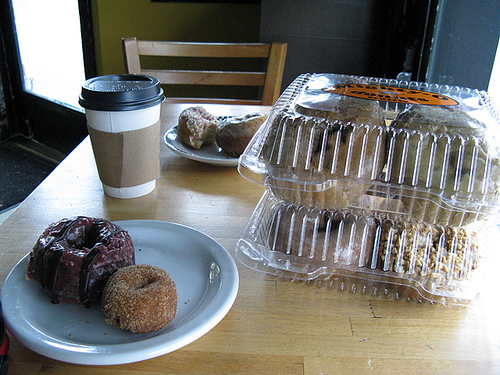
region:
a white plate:
[20, 204, 240, 371]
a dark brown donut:
[22, 205, 132, 293]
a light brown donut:
[93, 259, 183, 341]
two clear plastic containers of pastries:
[258, 67, 463, 316]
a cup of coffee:
[55, 31, 172, 219]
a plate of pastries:
[158, 92, 260, 167]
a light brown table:
[41, 84, 485, 359]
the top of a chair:
[73, 13, 295, 123]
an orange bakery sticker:
[327, 75, 461, 121]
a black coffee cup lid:
[68, 54, 168, 111]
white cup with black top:
[103, 100, 113, 130]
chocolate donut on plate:
[42, 250, 115, 285]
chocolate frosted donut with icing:
[39, 230, 135, 270]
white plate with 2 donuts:
[191, 256, 225, 304]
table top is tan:
[276, 320, 312, 331]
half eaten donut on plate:
[190, 113, 208, 163]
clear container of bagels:
[314, 135, 390, 182]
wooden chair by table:
[211, 43, 253, 87]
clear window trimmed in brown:
[33, 43, 55, 63]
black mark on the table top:
[348, 298, 395, 319]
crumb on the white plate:
[133, 243, 159, 253]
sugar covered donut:
[102, 267, 188, 321]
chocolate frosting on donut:
[30, 217, 129, 279]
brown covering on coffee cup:
[73, 118, 184, 186]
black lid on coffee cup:
[73, 68, 161, 110]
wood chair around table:
[114, 28, 304, 123]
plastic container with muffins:
[240, 65, 479, 219]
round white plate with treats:
[4, 217, 267, 354]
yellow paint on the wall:
[132, 9, 233, 23]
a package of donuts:
[240, 72, 495, 222]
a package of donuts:
[235, 176, 475, 306]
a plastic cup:
[80, 75, 162, 195]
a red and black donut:
[30, 212, 135, 307]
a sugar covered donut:
[102, 263, 177, 335]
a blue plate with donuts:
[4, 218, 239, 366]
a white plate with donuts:
[166, 105, 268, 165]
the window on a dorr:
[7, 0, 88, 112]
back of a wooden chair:
[120, 33, 280, 103]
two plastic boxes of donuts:
[232, 68, 498, 309]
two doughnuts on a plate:
[31, 210, 172, 333]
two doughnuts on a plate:
[175, 105, 253, 157]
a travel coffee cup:
[79, 69, 171, 204]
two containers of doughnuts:
[237, 89, 492, 306]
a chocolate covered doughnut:
[35, 212, 130, 282]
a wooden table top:
[263, 294, 415, 368]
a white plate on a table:
[174, 229, 249, 346]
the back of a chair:
[172, 28, 301, 98]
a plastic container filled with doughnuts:
[258, 203, 485, 320]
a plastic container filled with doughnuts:
[244, 77, 496, 208]